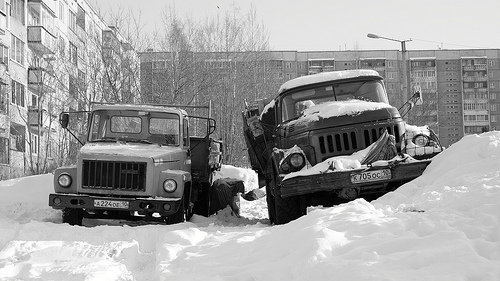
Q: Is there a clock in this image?
A: No, there are no clocks.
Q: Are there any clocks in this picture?
A: No, there are no clocks.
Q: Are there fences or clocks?
A: No, there are no clocks or fences.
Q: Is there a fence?
A: No, there are no fences.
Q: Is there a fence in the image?
A: No, there are no fences.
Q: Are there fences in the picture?
A: No, there are no fences.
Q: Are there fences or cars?
A: No, there are no fences or cars.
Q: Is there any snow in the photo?
A: Yes, there is snow.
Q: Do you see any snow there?
A: Yes, there is snow.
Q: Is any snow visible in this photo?
A: Yes, there is snow.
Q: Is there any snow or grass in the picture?
A: Yes, there is snow.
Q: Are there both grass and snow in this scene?
A: No, there is snow but no grass.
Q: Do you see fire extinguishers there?
A: No, there are no fire extinguishers.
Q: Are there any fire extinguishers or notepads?
A: No, there are no fire extinguishers or notepads.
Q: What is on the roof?
A: The snow is on the roof.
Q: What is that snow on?
A: The snow is on the roof.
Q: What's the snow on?
A: The snow is on the roof.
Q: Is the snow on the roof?
A: Yes, the snow is on the roof.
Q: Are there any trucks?
A: Yes, there is a truck.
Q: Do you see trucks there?
A: Yes, there is a truck.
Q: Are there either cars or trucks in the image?
A: Yes, there is a truck.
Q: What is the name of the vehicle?
A: The vehicle is a truck.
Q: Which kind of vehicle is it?
A: The vehicle is a truck.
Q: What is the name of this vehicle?
A: This is a truck.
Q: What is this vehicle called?
A: This is a truck.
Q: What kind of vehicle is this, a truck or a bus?
A: This is a truck.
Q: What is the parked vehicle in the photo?
A: The vehicle is a truck.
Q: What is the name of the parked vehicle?
A: The vehicle is a truck.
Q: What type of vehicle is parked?
A: The vehicle is a truck.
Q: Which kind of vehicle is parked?
A: The vehicle is a truck.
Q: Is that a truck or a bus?
A: That is a truck.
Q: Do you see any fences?
A: No, there are no fences.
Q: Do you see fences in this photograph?
A: No, there are no fences.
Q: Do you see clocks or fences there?
A: No, there are no fences or clocks.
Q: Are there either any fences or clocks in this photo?
A: No, there are no fences or clocks.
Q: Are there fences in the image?
A: No, there are no fences.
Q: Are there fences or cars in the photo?
A: No, there are no fences or cars.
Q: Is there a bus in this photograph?
A: No, there are no buses.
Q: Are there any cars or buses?
A: No, there are no buses or cars.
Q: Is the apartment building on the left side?
A: Yes, the apartment building is on the left of the image.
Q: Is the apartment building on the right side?
A: No, the apartment building is on the left of the image.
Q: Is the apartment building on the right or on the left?
A: The apartment building is on the left of the image.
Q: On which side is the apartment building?
A: The apartment building is on the left of the image.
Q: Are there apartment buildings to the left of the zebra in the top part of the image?
A: Yes, there is an apartment building to the left of the zebra.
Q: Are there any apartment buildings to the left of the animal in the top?
A: Yes, there is an apartment building to the left of the zebra.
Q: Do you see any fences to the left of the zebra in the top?
A: No, there is an apartment building to the left of the zebra.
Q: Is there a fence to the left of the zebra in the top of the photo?
A: No, there is an apartment building to the left of the zebra.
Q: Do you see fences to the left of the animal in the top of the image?
A: No, there is an apartment building to the left of the zebra.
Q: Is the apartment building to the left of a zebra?
A: Yes, the apartment building is to the left of a zebra.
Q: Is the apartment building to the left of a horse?
A: No, the apartment building is to the left of a zebra.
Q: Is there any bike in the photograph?
A: No, there are no bikes.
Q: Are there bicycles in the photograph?
A: No, there are no bicycles.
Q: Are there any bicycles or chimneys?
A: No, there are no bicycles or chimneys.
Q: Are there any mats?
A: No, there are no mats.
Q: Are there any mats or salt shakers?
A: No, there are no mats or salt shakers.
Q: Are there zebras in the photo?
A: Yes, there is a zebra.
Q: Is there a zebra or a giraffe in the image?
A: Yes, there is a zebra.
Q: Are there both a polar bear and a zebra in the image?
A: No, there is a zebra but no polar bears.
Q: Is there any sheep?
A: No, there is no sheep.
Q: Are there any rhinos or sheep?
A: No, there are no sheep or rhinos.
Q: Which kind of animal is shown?
A: The animal is a zebra.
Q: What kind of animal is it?
A: The animal is a zebra.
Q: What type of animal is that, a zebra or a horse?
A: This is a zebra.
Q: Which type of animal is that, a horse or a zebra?
A: This is a zebra.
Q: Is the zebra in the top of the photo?
A: Yes, the zebra is in the top of the image.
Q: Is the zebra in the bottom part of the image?
A: No, the zebra is in the top of the image.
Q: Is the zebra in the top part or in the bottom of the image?
A: The zebra is in the top of the image.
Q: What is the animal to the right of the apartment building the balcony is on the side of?
A: The animal is a zebra.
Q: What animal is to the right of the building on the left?
A: The animal is a zebra.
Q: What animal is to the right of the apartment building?
A: The animal is a zebra.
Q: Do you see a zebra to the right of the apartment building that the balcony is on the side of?
A: Yes, there is a zebra to the right of the apartment building.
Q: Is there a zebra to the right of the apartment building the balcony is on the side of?
A: Yes, there is a zebra to the right of the apartment building.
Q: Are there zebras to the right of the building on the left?
A: Yes, there is a zebra to the right of the apartment building.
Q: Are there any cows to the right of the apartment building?
A: No, there is a zebra to the right of the apartment building.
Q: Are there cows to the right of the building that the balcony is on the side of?
A: No, there is a zebra to the right of the apartment building.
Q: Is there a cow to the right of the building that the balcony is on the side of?
A: No, there is a zebra to the right of the apartment building.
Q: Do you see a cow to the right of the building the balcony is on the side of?
A: No, there is a zebra to the right of the apartment building.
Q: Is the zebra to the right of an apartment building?
A: Yes, the zebra is to the right of an apartment building.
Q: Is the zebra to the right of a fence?
A: No, the zebra is to the right of an apartment building.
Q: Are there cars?
A: No, there are no cars.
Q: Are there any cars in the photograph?
A: No, there are no cars.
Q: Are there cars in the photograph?
A: No, there are no cars.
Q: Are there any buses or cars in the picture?
A: No, there are no cars or buses.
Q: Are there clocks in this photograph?
A: No, there are no clocks.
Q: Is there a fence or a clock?
A: No, there are no clocks or fences.